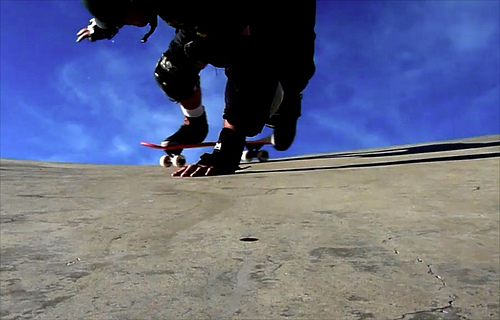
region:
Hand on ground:
[177, 164, 244, 183]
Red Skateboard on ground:
[135, 130, 295, 162]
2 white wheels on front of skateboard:
[154, 147, 186, 174]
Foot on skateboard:
[160, 106, 217, 150]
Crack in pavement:
[376, 222, 476, 317]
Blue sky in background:
[362, 40, 498, 142]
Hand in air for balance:
[71, 16, 153, 62]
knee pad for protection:
[150, 51, 205, 101]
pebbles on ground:
[68, 248, 83, 278]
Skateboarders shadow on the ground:
[309, 140, 498, 185]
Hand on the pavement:
[157, 96, 262, 203]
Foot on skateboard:
[135, 87, 225, 157]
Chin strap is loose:
[91, 0, 174, 56]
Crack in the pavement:
[360, 210, 490, 315]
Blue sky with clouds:
[355, 21, 465, 121]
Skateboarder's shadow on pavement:
[265, 140, 490, 170]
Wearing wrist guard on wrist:
[165, 110, 280, 185]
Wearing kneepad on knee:
[125, 40, 205, 100]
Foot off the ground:
[235, 75, 335, 160]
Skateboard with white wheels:
[123, 127, 313, 174]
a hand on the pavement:
[166, 150, 236, 180]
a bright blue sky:
[1, 3, 498, 165]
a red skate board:
[134, 128, 285, 168]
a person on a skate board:
[72, 0, 320, 180]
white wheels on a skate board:
[158, 150, 195, 175]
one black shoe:
[156, 114, 208, 154]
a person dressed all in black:
[76, 0, 320, 182]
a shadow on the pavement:
[233, 131, 498, 174]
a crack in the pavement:
[373, 222, 464, 319]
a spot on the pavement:
[236, 225, 265, 254]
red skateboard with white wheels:
[136, 126, 280, 171]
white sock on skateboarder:
[174, 98, 214, 121]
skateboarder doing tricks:
[57, 1, 367, 177]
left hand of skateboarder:
[172, 121, 259, 188]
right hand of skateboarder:
[67, 11, 132, 48]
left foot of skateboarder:
[158, 91, 216, 151]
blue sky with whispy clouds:
[323, 4, 498, 144]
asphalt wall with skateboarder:
[3, 151, 498, 317]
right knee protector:
[152, 45, 217, 107]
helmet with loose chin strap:
[75, 1, 177, 42]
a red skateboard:
[133, 135, 278, 168]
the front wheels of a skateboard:
[153, 145, 188, 173]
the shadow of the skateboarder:
[282, 133, 494, 188]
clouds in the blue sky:
[330, 13, 498, 129]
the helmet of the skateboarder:
[76, 5, 147, 37]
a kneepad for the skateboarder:
[143, 44, 198, 109]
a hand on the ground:
[179, 120, 251, 205]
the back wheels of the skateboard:
[244, 145, 273, 163]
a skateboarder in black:
[69, 1, 310, 133]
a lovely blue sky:
[10, 11, 74, 81]